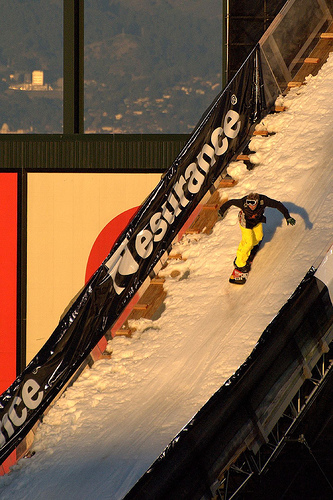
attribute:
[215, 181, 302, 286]
person — snow boarding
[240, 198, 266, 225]
sweater — black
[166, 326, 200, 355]
snow — white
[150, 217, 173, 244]
writing — white